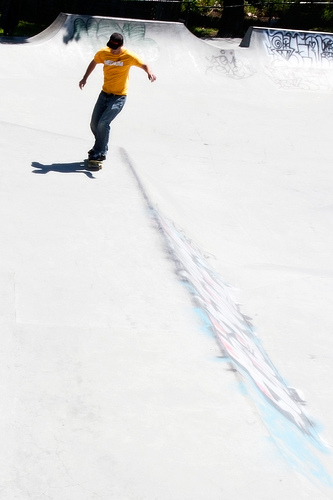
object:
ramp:
[247, 25, 332, 116]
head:
[105, 31, 122, 56]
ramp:
[121, 147, 333, 499]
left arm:
[125, 53, 148, 75]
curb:
[199, 35, 241, 43]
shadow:
[29, 160, 105, 179]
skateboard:
[82, 159, 100, 174]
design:
[266, 31, 332, 65]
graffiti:
[61, 15, 165, 49]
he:
[78, 29, 158, 162]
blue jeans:
[89, 88, 126, 160]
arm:
[85, 51, 101, 80]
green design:
[69, 15, 159, 68]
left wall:
[64, 17, 187, 114]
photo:
[0, 1, 332, 499]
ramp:
[63, 15, 186, 112]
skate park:
[0, 0, 332, 499]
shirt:
[93, 48, 141, 99]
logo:
[101, 57, 126, 68]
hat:
[105, 32, 124, 49]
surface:
[0, 0, 332, 498]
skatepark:
[0, 13, 332, 499]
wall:
[250, 27, 332, 93]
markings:
[151, 197, 332, 457]